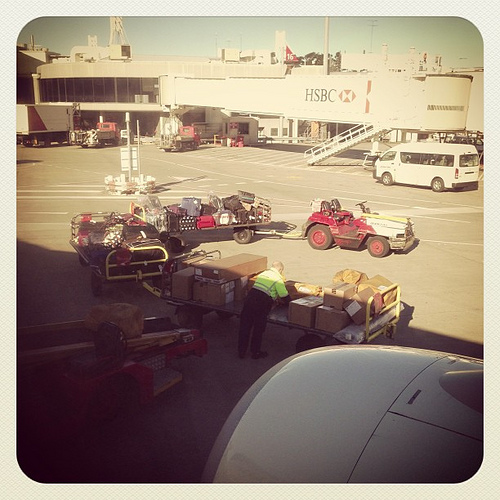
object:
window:
[142, 77, 159, 105]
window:
[126, 77, 137, 103]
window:
[114, 77, 126, 102]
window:
[90, 77, 103, 100]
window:
[65, 77, 73, 102]